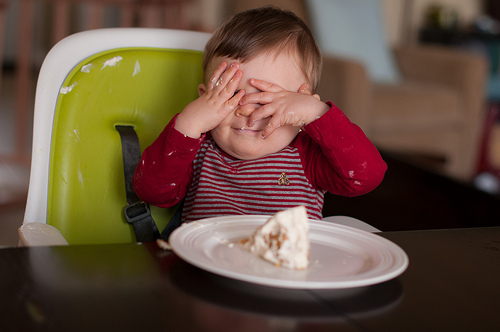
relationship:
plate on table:
[187, 219, 416, 299] [0, 227, 500, 329]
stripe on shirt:
[204, 160, 293, 170] [130, 98, 387, 223]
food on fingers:
[209, 73, 223, 92] [208, 58, 245, 113]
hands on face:
[173, 56, 330, 150] [205, 33, 312, 160]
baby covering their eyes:
[160, 0, 372, 210] [131, 0, 433, 327]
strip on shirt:
[212, 161, 261, 194] [151, 77, 411, 235]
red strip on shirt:
[218, 174, 252, 195] [160, 123, 346, 205]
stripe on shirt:
[196, 148, 217, 155] [130, 98, 387, 223]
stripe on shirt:
[199, 170, 309, 182] [135, 108, 386, 214]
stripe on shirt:
[194, 153, 300, 159] [130, 98, 387, 223]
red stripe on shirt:
[220, 195, 289, 212] [130, 98, 387, 223]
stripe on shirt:
[178, 201, 239, 210] [130, 98, 387, 223]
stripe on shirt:
[195, 181, 313, 198] [130, 98, 387, 223]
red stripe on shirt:
[131, 103, 386, 219] [130, 98, 387, 223]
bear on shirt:
[279, 172, 289, 183] [130, 98, 387, 223]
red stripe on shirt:
[271, 160, 299, 165] [130, 98, 387, 223]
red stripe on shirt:
[197, 149, 302, 164] [130, 98, 387, 223]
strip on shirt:
[254, 150, 310, 188] [130, 98, 387, 223]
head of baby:
[203, 12, 313, 169] [169, 4, 334, 254]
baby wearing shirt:
[131, 3, 388, 251] [130, 98, 387, 223]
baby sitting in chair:
[131, 3, 388, 251] [15, 20, 247, 236]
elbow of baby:
[130, 162, 181, 209] [131, 3, 388, 251]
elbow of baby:
[337, 147, 386, 195] [131, 3, 388, 251]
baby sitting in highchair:
[131, 3, 388, 251] [19, 25, 213, 243]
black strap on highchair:
[112, 125, 164, 244] [19, 25, 213, 243]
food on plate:
[243, 200, 315, 271] [168, 212, 411, 301]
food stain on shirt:
[340, 144, 357, 195] [130, 98, 387, 223]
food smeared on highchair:
[57, 56, 142, 95] [16, 25, 213, 248]